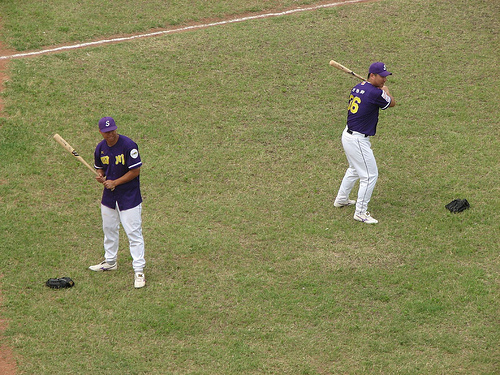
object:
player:
[332, 62, 396, 226]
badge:
[130, 147, 139, 159]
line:
[0, 0, 357, 63]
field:
[0, 0, 500, 375]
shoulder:
[116, 134, 139, 150]